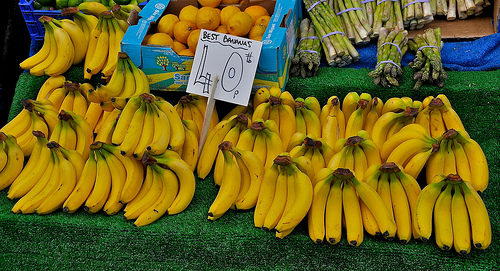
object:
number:
[194, 32, 253, 99]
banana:
[208, 143, 241, 217]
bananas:
[197, 87, 493, 254]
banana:
[134, 164, 179, 228]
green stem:
[460, 182, 471, 194]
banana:
[459, 181, 491, 249]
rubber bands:
[376, 42, 402, 57]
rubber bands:
[375, 61, 404, 73]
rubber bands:
[336, 7, 362, 16]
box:
[18, 0, 85, 73]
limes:
[35, 0, 64, 10]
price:
[192, 44, 243, 94]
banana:
[253, 164, 279, 228]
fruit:
[196, 6, 220, 30]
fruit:
[147, 33, 174, 48]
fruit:
[244, 6, 269, 23]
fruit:
[227, 12, 254, 36]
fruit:
[187, 29, 201, 52]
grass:
[97, 244, 372, 271]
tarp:
[341, 33, 499, 71]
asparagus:
[408, 27, 447, 91]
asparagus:
[368, 26, 409, 88]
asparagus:
[302, 0, 360, 67]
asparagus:
[291, 18, 322, 78]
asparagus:
[337, 0, 373, 45]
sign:
[185, 29, 263, 108]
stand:
[0, 0, 493, 270]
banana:
[308, 176, 336, 244]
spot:
[153, 209, 158, 213]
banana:
[44, 22, 74, 77]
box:
[119, 0, 303, 94]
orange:
[174, 20, 196, 44]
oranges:
[142, 0, 270, 56]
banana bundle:
[207, 140, 266, 221]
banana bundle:
[253, 152, 314, 239]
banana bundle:
[308, 168, 395, 248]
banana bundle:
[413, 173, 491, 255]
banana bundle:
[63, 141, 145, 216]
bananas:
[0, 42, 218, 228]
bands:
[321, 31, 346, 43]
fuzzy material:
[0, 226, 127, 271]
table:
[452, 71, 498, 88]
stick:
[198, 74, 220, 158]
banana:
[248, 165, 273, 226]